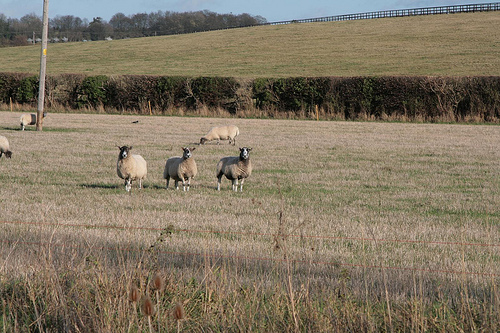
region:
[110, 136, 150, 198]
a white sheep in a field.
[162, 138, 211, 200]
a dark sheep in a field.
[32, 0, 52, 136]
a pole in a field.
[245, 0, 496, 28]
a long fence on a hilltop.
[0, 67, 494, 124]
a cliff on a green hill.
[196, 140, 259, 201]
a sheep standing on grass.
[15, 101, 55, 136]
a sheep standing near a pole.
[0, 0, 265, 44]
a lush green forest of trees.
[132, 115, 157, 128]
a black section of the field.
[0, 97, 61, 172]
two sheep.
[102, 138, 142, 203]
sheep standing in grass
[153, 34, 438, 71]
large grassy field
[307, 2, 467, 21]
bridge by large grassy field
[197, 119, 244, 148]
sheep eating green grass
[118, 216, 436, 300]
red wire to keep sheep in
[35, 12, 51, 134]
pole in sheep field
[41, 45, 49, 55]
yellow spot on pole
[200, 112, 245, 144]
white sheep eating grass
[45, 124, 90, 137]
green grass near pole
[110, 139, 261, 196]
three sheep in a row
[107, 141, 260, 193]
three sheep walking in the grass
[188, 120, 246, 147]
one sheep grazing in the grass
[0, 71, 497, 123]
row of thick green bushes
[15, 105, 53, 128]
sheep standing behind a poll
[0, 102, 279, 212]
herd of sheep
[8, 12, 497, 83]
empty field behind the row of bushes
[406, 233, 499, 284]
two thin parellel wires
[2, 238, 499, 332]
patch of tall grass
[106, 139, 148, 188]
fuzzy white sheep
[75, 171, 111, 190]
shadow in the grass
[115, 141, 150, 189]
a off white an tan sheep looking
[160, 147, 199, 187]
a off white an tan sheep looking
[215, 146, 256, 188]
a off white an tan sheep looking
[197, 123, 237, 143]
a off white an tan sheep eating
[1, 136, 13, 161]
a off white an tan sheep eating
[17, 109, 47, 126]
a off white an tan sheep standing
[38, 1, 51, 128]
a tall wooden pole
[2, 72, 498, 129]
a long green and brown hedge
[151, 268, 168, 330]
a top of a piece of grass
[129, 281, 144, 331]
a top of a piece of grass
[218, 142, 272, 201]
this is a sheep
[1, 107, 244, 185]
they are six sheep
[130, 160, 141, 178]
the wool is white in color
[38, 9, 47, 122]
this is a pole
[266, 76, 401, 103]
this is a fence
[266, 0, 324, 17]
this is the sky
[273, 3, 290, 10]
the sky is blue in color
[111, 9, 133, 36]
this is a tree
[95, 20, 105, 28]
the tree has green leaves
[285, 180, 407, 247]
this is a grass area